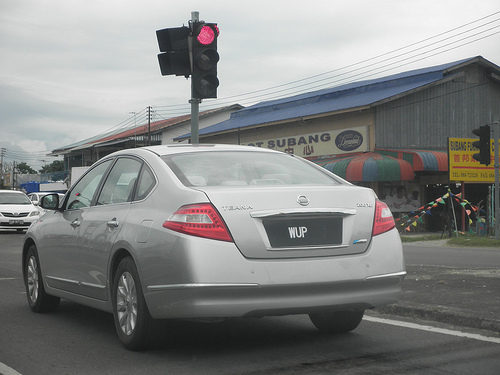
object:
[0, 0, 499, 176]
sky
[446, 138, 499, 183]
sign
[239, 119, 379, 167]
writing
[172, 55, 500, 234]
building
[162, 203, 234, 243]
light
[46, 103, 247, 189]
building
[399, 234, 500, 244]
grass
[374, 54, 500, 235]
front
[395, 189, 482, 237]
flags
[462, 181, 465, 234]
poles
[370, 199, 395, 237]
light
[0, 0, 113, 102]
clouds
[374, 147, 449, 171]
awning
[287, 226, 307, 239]
letters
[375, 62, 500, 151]
wall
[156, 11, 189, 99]
light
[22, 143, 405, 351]
car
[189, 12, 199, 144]
pole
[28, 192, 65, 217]
car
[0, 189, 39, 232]
car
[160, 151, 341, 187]
window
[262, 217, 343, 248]
numberplates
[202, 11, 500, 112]
wires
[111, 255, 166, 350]
tire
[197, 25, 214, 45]
red light